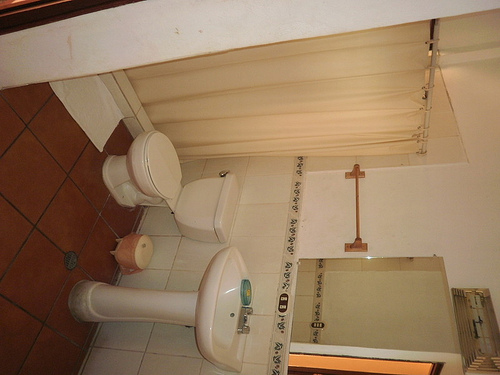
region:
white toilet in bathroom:
[106, 135, 236, 241]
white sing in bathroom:
[76, 245, 261, 366]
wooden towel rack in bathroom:
[341, 165, 368, 250]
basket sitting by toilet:
[111, 233, 151, 270]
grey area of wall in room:
[288, 257, 463, 351]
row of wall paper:
[268, 151, 305, 368]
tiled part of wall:
[94, 162, 296, 369]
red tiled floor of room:
[0, 83, 217, 365]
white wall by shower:
[304, 155, 498, 285]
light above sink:
[451, 285, 498, 359]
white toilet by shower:
[107, 137, 235, 240]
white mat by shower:
[46, 72, 132, 149]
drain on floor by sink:
[61, 252, 79, 269]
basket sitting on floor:
[115, 225, 155, 273]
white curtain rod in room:
[423, 15, 439, 154]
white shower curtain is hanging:
[125, 22, 440, 159]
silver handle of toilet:
[217, 168, 234, 179]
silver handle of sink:
[237, 303, 254, 336]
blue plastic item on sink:
[241, 280, 253, 307]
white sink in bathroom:
[67, 243, 260, 369]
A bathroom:
[3, 1, 494, 371]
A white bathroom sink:
[70, 245, 250, 365]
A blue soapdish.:
[240, 280, 255, 300]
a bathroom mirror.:
[290, 256, 465, 356]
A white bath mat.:
[45, 75, 125, 150]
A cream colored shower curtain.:
[120, 55, 420, 155]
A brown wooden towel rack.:
[345, 160, 366, 250]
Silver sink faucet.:
[235, 302, 252, 332]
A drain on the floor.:
[59, 250, 79, 272]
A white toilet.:
[103, 128, 240, 247]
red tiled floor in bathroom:
[6, 88, 187, 366]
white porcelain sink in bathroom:
[48, 246, 258, 365]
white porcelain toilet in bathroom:
[92, 126, 257, 244]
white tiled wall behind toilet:
[79, 149, 303, 373]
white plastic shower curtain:
[110, 15, 477, 176]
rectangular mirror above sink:
[286, 253, 457, 354]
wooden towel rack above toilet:
[339, 163, 374, 254]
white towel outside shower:
[44, 73, 124, 151]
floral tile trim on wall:
[265, 158, 307, 374]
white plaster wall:
[2, 6, 499, 96]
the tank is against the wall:
[180, 175, 239, 240]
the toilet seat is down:
[138, 125, 183, 201]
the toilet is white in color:
[107, 131, 236, 243]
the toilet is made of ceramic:
[106, 128, 240, 244]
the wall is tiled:
[98, 145, 309, 373]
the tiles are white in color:
[100, 142, 305, 374]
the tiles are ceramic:
[84, 143, 303, 373]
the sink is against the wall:
[201, 238, 247, 374]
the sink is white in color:
[201, 245, 253, 369]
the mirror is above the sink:
[290, 258, 462, 354]